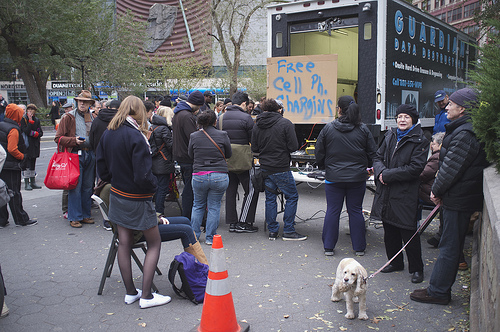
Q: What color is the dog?
A: White.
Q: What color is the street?
A: Black.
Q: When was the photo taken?
A: Daytime.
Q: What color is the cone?
A: Orange and white.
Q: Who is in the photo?
A: People.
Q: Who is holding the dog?
A: A guy.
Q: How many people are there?
A: More than ten.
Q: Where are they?
A: In a parking lot.